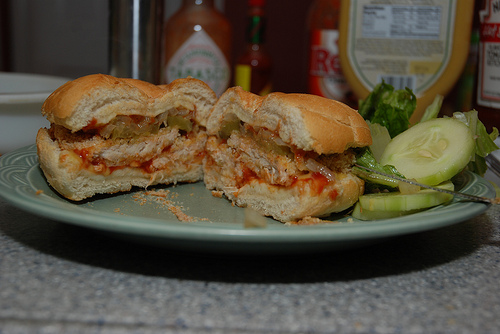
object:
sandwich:
[201, 83, 377, 230]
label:
[345, 3, 457, 99]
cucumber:
[373, 117, 470, 187]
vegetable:
[351, 182, 455, 219]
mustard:
[455, 6, 469, 54]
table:
[0, 99, 498, 334]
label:
[162, 30, 229, 92]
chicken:
[265, 159, 288, 177]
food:
[32, 70, 487, 218]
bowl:
[1, 73, 71, 151]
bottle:
[339, 0, 469, 117]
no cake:
[38, 59, 481, 221]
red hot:
[211, 25, 229, 42]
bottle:
[157, 4, 234, 95]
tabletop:
[1, 301, 36, 332]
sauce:
[162, 7, 232, 92]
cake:
[36, 73, 218, 202]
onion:
[316, 164, 335, 184]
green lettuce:
[362, 75, 417, 126]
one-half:
[203, 86, 372, 218]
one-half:
[37, 74, 218, 201]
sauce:
[315, 178, 325, 183]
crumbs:
[166, 196, 169, 198]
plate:
[0, 144, 495, 261]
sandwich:
[35, 71, 213, 200]